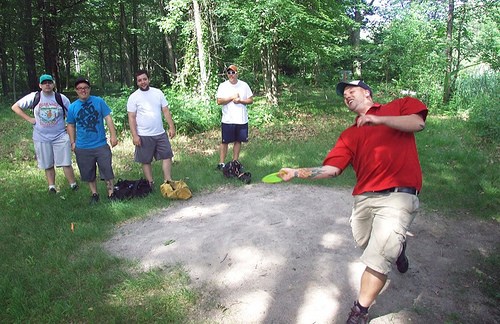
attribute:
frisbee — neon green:
[256, 163, 306, 189]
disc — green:
[259, 170, 285, 187]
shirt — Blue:
[61, 94, 111, 151]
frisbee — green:
[261, 170, 286, 183]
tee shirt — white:
[213, 77, 255, 125]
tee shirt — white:
[124, 86, 170, 136]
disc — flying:
[259, 169, 292, 188]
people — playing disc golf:
[8, 58, 437, 322]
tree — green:
[157, 2, 225, 118]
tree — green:
[368, 9, 443, 94]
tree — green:
[433, 0, 489, 112]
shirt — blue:
[65, 103, 105, 143]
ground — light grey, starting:
[146, 191, 352, 323]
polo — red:
[325, 97, 428, 193]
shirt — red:
[320, 97, 427, 189]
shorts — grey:
[349, 186, 419, 276]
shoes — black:
[343, 236, 410, 322]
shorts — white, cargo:
[346, 192, 445, 281]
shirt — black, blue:
[58, 95, 115, 151]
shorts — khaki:
[317, 177, 425, 273]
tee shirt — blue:
[67, 99, 112, 149]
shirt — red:
[320, 92, 430, 197]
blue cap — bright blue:
[26, 72, 59, 85]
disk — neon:
[260, 172, 282, 184]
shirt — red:
[325, 97, 430, 194]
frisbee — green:
[259, 160, 290, 191]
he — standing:
[269, 85, 421, 317]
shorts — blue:
[219, 117, 248, 147]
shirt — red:
[327, 99, 441, 194]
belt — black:
[375, 187, 421, 199]